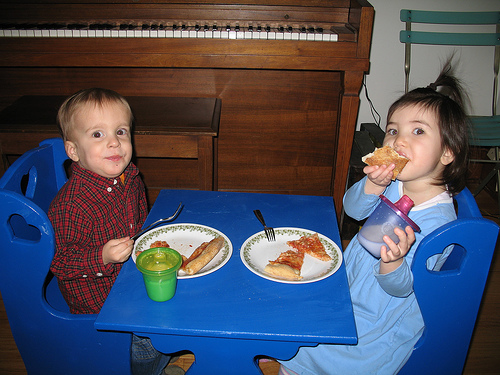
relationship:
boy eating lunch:
[47, 84, 156, 312] [131, 212, 234, 278]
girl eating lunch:
[275, 89, 455, 371] [241, 220, 344, 285]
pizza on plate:
[269, 243, 306, 278] [241, 220, 344, 285]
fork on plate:
[251, 203, 279, 241] [242, 229, 346, 279]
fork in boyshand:
[132, 201, 191, 245] [59, 237, 133, 273]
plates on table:
[129, 211, 346, 295] [96, 180, 359, 359]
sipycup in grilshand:
[362, 187, 418, 262] [365, 233, 438, 307]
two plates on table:
[129, 211, 346, 295] [96, 180, 359, 359]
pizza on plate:
[269, 243, 306, 278] [242, 229, 346, 279]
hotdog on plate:
[163, 237, 225, 268] [242, 229, 346, 279]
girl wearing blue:
[275, 89, 455, 371] [310, 190, 445, 374]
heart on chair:
[425, 244, 481, 284] [0, 139, 57, 374]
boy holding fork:
[47, 84, 156, 312] [132, 201, 191, 245]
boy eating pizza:
[47, 84, 156, 312] [269, 243, 306, 278]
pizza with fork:
[269, 243, 306, 278] [251, 203, 279, 241]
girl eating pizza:
[275, 89, 455, 371] [269, 243, 306, 278]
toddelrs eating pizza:
[242, 229, 346, 279] [269, 243, 306, 278]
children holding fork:
[47, 84, 156, 312] [132, 201, 191, 245]